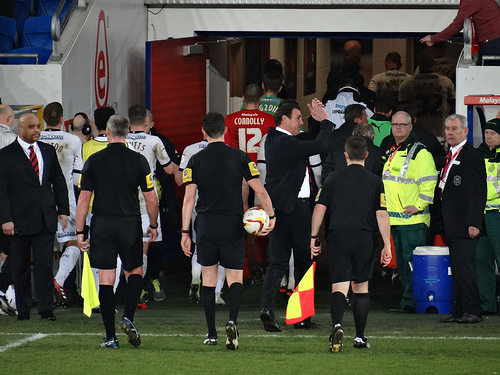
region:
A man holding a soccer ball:
[174, 107, 281, 359]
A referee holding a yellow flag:
[59, 114, 180, 358]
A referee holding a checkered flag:
[275, 120, 412, 365]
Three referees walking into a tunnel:
[60, 107, 404, 358]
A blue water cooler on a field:
[404, 225, 472, 330]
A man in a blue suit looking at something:
[1, 104, 73, 331]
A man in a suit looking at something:
[431, 112, 496, 313]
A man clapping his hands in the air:
[258, 87, 337, 354]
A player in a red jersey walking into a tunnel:
[216, 75, 284, 189]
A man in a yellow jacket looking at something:
[372, 102, 442, 330]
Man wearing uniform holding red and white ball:
[180, 110, 276, 350]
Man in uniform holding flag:
[282, 135, 389, 350]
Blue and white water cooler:
[405, 245, 450, 315]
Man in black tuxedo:
[0, 110, 70, 320]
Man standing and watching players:
[431, 111, 486, 321]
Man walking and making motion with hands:
[255, 95, 330, 330]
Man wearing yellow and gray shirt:
[380, 110, 435, 310]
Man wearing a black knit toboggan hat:
[475, 115, 495, 315]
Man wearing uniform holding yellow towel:
[74, 111, 159, 349]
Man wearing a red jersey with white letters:
[225, 82, 275, 285]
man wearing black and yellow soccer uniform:
[72, 146, 164, 268]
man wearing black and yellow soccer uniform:
[162, 133, 263, 283]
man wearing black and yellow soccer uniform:
[302, 160, 391, 276]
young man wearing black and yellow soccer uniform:
[67, 148, 169, 327]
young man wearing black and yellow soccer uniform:
[174, 143, 271, 353]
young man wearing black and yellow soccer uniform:
[319, 153, 400, 334]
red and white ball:
[227, 210, 268, 246]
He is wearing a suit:
[0, 112, 70, 320]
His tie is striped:
[0, 112, 72, 322]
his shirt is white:
[0, 110, 70, 320]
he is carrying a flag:
[283, 137, 393, 352]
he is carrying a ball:
[180, 112, 276, 351]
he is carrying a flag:
[74, 113, 160, 347]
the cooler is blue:
[408, 244, 455, 314]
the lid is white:
[408, 246, 453, 314]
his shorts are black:
[181, 111, 276, 347]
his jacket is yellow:
[381, 108, 437, 310]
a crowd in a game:
[4, 80, 498, 351]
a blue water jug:
[407, 240, 463, 317]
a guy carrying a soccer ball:
[172, 110, 279, 353]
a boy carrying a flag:
[279, 129, 399, 356]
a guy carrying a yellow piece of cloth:
[66, 110, 167, 352]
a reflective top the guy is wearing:
[378, 145, 438, 227]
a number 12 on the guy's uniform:
[234, 124, 263, 156]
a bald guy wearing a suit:
[1, 109, 73, 325]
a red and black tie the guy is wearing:
[28, 145, 41, 166]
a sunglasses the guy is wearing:
[388, 120, 410, 129]